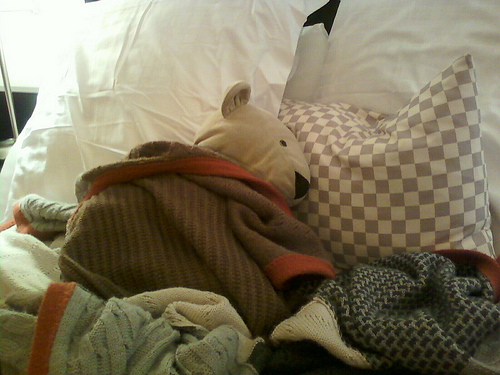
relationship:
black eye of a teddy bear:
[278, 140, 288, 147] [113, 104, 321, 269]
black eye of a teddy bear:
[278, 131, 294, 155] [197, 63, 341, 321]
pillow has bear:
[278, 52, 497, 271] [192, 78, 310, 206]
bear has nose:
[191, 78, 312, 208] [293, 171, 312, 201]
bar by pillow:
[1, 55, 19, 142] [0, 0, 330, 229]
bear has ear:
[191, 78, 312, 208] [216, 80, 251, 117]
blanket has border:
[55, 140, 337, 337] [82, 155, 296, 217]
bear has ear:
[192, 78, 310, 206] [220, 78, 252, 115]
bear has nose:
[192, 78, 310, 206] [289, 170, 313, 201]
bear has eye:
[192, 78, 310, 206] [278, 138, 288, 148]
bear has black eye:
[192, 78, 310, 206] [278, 140, 288, 147]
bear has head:
[192, 78, 310, 206] [190, 78, 312, 209]